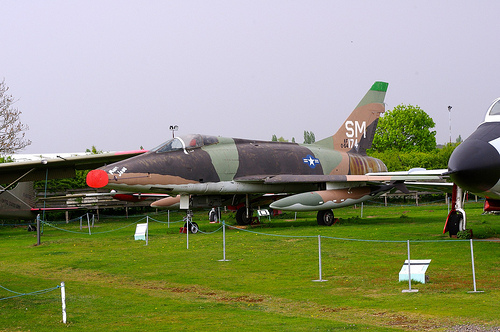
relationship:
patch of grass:
[238, 242, 308, 284] [1, 190, 497, 329]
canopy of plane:
[150, 132, 204, 154] [84, 76, 449, 233]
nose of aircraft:
[438, 138, 498, 195] [442, 99, 497, 213]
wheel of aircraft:
[448, 210, 463, 234] [442, 96, 500, 237]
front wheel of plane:
[183, 220, 203, 237] [86, 68, 443, 235]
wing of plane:
[238, 165, 447, 187] [84, 76, 449, 233]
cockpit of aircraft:
[159, 137, 209, 159] [74, 93, 419, 190]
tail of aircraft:
[308, 81, 388, 156] [88, 80, 390, 232]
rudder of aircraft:
[351, 101, 386, 148] [88, 80, 390, 232]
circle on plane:
[303, 153, 316, 169] [84, 76, 449, 233]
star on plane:
[303, 149, 316, 165] [84, 76, 449, 233]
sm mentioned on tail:
[337, 118, 375, 142] [314, 81, 388, 149]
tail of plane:
[314, 81, 388, 149] [84, 76, 449, 233]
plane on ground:
[84, 76, 449, 233] [0, 196, 497, 330]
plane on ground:
[77, 76, 466, 244] [0, 234, 298, 329]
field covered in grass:
[3, 195, 499, 330] [30, 222, 410, 330]